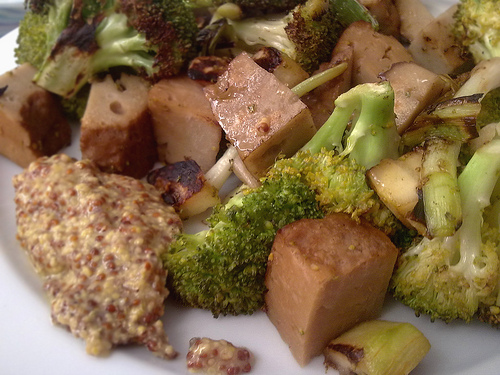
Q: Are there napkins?
A: No, there are no napkins.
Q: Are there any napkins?
A: No, there are no napkins.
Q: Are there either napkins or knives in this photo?
A: No, there are no napkins or knives.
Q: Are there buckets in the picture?
A: No, there are no buckets.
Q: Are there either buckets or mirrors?
A: No, there are no buckets or mirrors.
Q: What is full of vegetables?
A: The dish is full of vegetables.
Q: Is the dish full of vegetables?
A: Yes, the dish is full of vegetables.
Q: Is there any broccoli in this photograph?
A: Yes, there is broccoli.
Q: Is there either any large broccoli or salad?
A: Yes, there is large broccoli.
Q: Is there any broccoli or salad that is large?
A: Yes, the broccoli is large.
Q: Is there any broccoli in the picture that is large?
A: Yes, there is broccoli that is large.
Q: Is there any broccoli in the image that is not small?
A: Yes, there is large broccoli.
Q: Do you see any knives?
A: No, there are no knives.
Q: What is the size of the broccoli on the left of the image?
A: The broccoli is large.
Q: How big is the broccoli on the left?
A: The broccoli is large.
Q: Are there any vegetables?
A: Yes, there are vegetables.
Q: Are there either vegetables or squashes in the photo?
A: Yes, there are vegetables.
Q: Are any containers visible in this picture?
A: No, there are no containers.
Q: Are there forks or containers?
A: No, there are no containers or forks.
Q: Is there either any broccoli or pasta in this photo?
A: Yes, there is broccoli.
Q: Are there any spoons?
A: No, there are no spoons.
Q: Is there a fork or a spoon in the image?
A: No, there are no spoons or forks.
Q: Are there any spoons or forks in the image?
A: No, there are no spoons or forks.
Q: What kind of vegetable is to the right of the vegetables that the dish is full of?
A: The vegetable is broccoli.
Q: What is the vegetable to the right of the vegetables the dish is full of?
A: The vegetable is broccoli.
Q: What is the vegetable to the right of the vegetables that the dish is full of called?
A: The vegetable is broccoli.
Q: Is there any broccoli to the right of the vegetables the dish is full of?
A: Yes, there is broccoli to the right of the veggies.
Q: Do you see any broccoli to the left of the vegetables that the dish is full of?
A: No, the broccoli is to the right of the vegetables.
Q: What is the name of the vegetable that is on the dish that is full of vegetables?
A: The vegetable is broccoli.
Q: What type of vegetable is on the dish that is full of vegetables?
A: The vegetable is broccoli.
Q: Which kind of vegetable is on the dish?
A: The vegetable is broccoli.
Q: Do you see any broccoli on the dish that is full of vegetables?
A: Yes, there is broccoli on the dish.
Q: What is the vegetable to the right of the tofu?
A: The vegetable is broccoli.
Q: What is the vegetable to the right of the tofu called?
A: The vegetable is broccoli.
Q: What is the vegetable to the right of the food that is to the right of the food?
A: The vegetable is broccoli.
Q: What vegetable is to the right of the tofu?
A: The vegetable is broccoli.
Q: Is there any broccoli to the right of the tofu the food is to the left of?
A: Yes, there is broccoli to the right of the tofu.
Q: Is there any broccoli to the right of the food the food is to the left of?
A: Yes, there is broccoli to the right of the tofu.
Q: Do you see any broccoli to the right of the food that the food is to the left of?
A: Yes, there is broccoli to the right of the tofu.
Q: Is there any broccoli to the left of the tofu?
A: No, the broccoli is to the right of the tofu.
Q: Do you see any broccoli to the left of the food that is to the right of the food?
A: No, the broccoli is to the right of the tofu.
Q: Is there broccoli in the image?
A: Yes, there is broccoli.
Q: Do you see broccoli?
A: Yes, there is broccoli.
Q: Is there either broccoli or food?
A: Yes, there is broccoli.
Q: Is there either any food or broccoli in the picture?
A: Yes, there is broccoli.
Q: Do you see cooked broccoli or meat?
A: Yes, there is cooked broccoli.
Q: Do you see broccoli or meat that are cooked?
A: Yes, the broccoli is cooked.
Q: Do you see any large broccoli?
A: Yes, there is large broccoli.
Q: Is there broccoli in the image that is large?
A: Yes, there is broccoli that is large.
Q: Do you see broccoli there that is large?
A: Yes, there is broccoli that is large.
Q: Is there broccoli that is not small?
A: Yes, there is large broccoli.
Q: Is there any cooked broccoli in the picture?
A: Yes, there is cooked broccoli.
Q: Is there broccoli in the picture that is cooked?
A: Yes, there is broccoli that is cooked.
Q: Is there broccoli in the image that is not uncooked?
A: Yes, there is cooked broccoli.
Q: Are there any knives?
A: No, there are no knives.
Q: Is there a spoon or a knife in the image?
A: No, there are no knives or spoons.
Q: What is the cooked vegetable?
A: The vegetable is broccoli.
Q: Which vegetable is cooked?
A: The vegetable is broccoli.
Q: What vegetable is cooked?
A: The vegetable is broccoli.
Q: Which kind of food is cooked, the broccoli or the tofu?
A: The broccoli is cooked.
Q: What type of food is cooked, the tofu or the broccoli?
A: The broccoli is cooked.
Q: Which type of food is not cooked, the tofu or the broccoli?
A: The tofu is not cooked.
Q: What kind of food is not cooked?
A: The food is tofu.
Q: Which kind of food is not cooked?
A: The food is tofu.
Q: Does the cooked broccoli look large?
A: Yes, the broccoli is large.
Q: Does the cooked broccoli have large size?
A: Yes, the broccoli is large.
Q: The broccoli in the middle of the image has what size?
A: The broccoli is large.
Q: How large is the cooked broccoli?
A: The broccoli is large.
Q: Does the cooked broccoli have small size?
A: No, the broccoli is large.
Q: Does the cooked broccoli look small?
A: No, the broccoli is large.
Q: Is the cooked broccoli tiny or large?
A: The broccoli is large.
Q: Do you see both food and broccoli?
A: Yes, there are both broccoli and food.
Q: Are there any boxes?
A: No, there are no boxes.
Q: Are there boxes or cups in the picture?
A: No, there are no boxes or cups.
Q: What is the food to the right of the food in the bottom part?
A: The food is tofu.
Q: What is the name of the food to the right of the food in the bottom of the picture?
A: The food is tofu.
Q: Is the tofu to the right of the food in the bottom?
A: Yes, the tofu is to the right of the food.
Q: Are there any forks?
A: No, there are no forks.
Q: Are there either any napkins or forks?
A: No, there are no forks or napkins.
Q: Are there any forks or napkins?
A: No, there are no forks or napkins.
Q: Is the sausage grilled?
A: Yes, the sausage is grilled.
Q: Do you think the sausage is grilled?
A: Yes, the sausage is grilled.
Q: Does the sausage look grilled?
A: Yes, the sausage is grilled.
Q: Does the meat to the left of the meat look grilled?
A: Yes, the sausage is grilled.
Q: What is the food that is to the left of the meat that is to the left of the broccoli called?
A: The food is a sausage.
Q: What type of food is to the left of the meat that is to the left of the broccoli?
A: The food is a sausage.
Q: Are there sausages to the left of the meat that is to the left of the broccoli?
A: Yes, there is a sausage to the left of the meat.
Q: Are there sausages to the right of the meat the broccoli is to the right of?
A: No, the sausage is to the left of the meat.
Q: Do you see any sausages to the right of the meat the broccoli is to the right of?
A: No, the sausage is to the left of the meat.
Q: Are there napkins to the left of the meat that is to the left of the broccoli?
A: No, there is a sausage to the left of the meat.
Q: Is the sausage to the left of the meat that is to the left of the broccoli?
A: Yes, the sausage is to the left of the meat.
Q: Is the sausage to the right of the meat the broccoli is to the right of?
A: No, the sausage is to the left of the meat.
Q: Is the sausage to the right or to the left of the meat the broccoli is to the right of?
A: The sausage is to the left of the meat.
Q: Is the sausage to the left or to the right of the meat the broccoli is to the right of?
A: The sausage is to the left of the meat.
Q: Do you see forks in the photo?
A: No, there are no forks.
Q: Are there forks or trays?
A: No, there are no forks or trays.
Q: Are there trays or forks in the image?
A: No, there are no forks or trays.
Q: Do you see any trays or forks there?
A: No, there are no forks or trays.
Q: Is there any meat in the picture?
A: Yes, there is meat.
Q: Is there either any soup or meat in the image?
A: Yes, there is meat.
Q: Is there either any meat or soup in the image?
A: Yes, there is meat.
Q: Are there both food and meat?
A: Yes, there are both meat and food.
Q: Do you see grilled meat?
A: Yes, there is grilled meat.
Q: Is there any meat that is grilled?
A: Yes, there is grilled meat.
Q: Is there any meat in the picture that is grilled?
A: Yes, there is meat that is grilled.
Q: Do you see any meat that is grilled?
A: Yes, there is meat that is grilled.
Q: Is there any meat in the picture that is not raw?
A: Yes, there is grilled meat.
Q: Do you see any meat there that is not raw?
A: Yes, there is grilled meat.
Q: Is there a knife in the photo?
A: No, there are no knives.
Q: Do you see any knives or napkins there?
A: No, there are no knives or napkins.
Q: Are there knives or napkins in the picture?
A: No, there are no knives or napkins.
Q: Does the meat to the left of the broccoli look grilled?
A: Yes, the meat is grilled.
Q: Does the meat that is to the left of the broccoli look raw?
A: No, the meat is grilled.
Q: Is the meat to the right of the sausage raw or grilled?
A: The meat is grilled.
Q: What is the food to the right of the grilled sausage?
A: The food is meat.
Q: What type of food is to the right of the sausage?
A: The food is meat.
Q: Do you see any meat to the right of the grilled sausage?
A: Yes, there is meat to the right of the sausage.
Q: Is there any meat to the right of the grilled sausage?
A: Yes, there is meat to the right of the sausage.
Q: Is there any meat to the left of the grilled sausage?
A: No, the meat is to the right of the sausage.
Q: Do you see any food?
A: Yes, there is food.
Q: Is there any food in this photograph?
A: Yes, there is food.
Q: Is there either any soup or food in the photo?
A: Yes, there is food.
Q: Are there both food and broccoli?
A: Yes, there are both food and broccoli.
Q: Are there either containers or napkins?
A: No, there are no napkins or containers.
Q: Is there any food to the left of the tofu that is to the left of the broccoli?
A: Yes, there is food to the left of the tofu.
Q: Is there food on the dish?
A: Yes, there is food on the dish.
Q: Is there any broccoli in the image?
A: Yes, there is broccoli.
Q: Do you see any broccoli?
A: Yes, there is broccoli.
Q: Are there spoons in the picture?
A: No, there are no spoons.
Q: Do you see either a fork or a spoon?
A: No, there are no spoons or forks.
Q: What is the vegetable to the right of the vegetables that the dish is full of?
A: The vegetable is broccoli.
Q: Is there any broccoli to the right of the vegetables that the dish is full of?
A: Yes, there is broccoli to the right of the veggies.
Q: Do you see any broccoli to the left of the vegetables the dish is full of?
A: No, the broccoli is to the right of the vegetables.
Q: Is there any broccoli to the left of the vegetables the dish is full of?
A: No, the broccoli is to the right of the vegetables.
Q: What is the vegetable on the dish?
A: The vegetable is broccoli.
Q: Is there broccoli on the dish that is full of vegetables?
A: Yes, there is broccoli on the dish.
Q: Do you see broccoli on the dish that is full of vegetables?
A: Yes, there is broccoli on the dish.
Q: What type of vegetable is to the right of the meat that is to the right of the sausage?
A: The vegetable is broccoli.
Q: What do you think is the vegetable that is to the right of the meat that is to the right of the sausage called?
A: The vegetable is broccoli.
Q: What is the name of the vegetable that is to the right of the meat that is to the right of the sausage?
A: The vegetable is broccoli.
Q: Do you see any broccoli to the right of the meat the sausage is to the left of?
A: Yes, there is broccoli to the right of the meat.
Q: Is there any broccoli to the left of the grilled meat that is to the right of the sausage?
A: No, the broccoli is to the right of the meat.